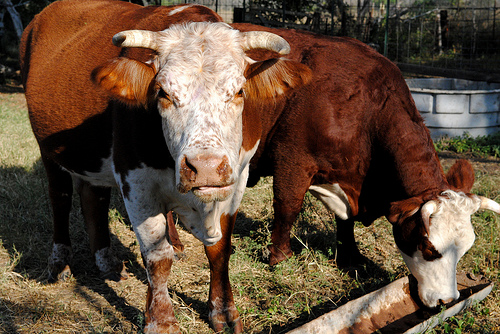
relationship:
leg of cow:
[267, 154, 317, 264] [251, 24, 500, 311]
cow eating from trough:
[251, 24, 500, 311] [278, 269, 489, 333]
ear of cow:
[242, 55, 317, 105] [17, 2, 317, 332]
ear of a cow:
[90, 58, 158, 108] [17, 2, 317, 332]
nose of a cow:
[177, 153, 236, 188] [17, 2, 317, 332]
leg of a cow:
[122, 189, 188, 334] [17, 2, 317, 332]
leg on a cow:
[206, 205, 241, 333] [17, 2, 317, 332]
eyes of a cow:
[235, 88, 245, 98] [17, 2, 317, 332]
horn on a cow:
[111, 29, 159, 53] [17, 2, 317, 332]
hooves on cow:
[143, 308, 248, 334] [17, 2, 317, 332]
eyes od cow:
[156, 87, 246, 103] [17, 2, 317, 332]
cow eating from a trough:
[251, 24, 500, 311] [278, 269, 489, 333]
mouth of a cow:
[178, 179, 236, 202] [17, 2, 317, 332]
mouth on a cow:
[178, 179, 236, 202] [17, 2, 317, 332]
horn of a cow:
[421, 200, 437, 234] [251, 24, 500, 311]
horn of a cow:
[476, 194, 499, 214] [251, 24, 500, 311]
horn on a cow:
[243, 28, 291, 57] [17, 2, 317, 332]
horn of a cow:
[111, 29, 165, 53] [17, 2, 317, 332]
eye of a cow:
[156, 81, 176, 106] [17, 2, 317, 332]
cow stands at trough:
[17, 2, 317, 332] [278, 269, 489, 333]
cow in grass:
[17, 2, 317, 332] [1, 90, 348, 334]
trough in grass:
[278, 269, 489, 333] [1, 90, 348, 334]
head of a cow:
[384, 160, 499, 311] [251, 24, 500, 311]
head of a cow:
[91, 22, 314, 201] [17, 2, 317, 332]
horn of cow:
[111, 29, 165, 53] [17, 2, 317, 332]